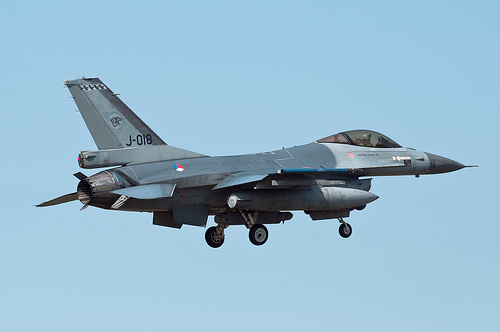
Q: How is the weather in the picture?
A: It is clear.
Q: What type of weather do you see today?
A: It is clear.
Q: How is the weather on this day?
A: It is clear.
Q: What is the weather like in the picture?
A: It is clear.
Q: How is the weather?
A: It is clear.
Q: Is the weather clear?
A: Yes, it is clear.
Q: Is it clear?
A: Yes, it is clear.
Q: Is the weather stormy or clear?
A: It is clear.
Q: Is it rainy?
A: No, it is clear.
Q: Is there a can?
A: No, there are no cans.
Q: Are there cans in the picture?
A: No, there are no cans.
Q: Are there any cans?
A: No, there are no cans.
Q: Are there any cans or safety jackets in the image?
A: No, there are no cans or safety jackets.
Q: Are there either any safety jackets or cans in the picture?
A: No, there are no cans or safety jackets.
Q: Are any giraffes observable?
A: No, there are no giraffes.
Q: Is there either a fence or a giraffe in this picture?
A: No, there are no giraffes or fences.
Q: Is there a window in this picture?
A: Yes, there is a window.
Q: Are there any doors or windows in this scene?
A: Yes, there is a window.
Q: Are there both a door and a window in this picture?
A: No, there is a window but no doors.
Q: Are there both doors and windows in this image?
A: No, there is a window but no doors.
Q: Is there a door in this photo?
A: No, there are no doors.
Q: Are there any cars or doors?
A: No, there are no doors or cars.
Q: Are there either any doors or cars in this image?
A: No, there are no doors or cars.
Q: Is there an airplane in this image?
A: Yes, there is an airplane.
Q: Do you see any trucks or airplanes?
A: Yes, there is an airplane.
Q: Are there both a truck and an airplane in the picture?
A: No, there is an airplane but no trucks.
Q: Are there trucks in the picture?
A: No, there are no trucks.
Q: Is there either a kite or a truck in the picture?
A: No, there are no trucks or kites.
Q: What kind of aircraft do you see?
A: The aircraft is an airplane.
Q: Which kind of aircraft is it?
A: The aircraft is an airplane.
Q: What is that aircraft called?
A: This is an airplane.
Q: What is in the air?
A: The plane is in the air.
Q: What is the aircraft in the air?
A: The aircraft is an airplane.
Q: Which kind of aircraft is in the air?
A: The aircraft is an airplane.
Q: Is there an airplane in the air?
A: Yes, there is an airplane in the air.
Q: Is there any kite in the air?
A: No, there is an airplane in the air.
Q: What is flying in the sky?
A: The airplane is flying in the sky.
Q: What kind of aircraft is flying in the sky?
A: The aircraft is an airplane.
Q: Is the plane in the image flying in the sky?
A: Yes, the plane is flying in the sky.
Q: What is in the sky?
A: The airplane is in the sky.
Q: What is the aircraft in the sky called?
A: The aircraft is an airplane.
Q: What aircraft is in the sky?
A: The aircraft is an airplane.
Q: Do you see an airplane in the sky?
A: Yes, there is an airplane in the sky.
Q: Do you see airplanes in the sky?
A: Yes, there is an airplane in the sky.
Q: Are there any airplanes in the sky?
A: Yes, there is an airplane in the sky.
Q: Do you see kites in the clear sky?
A: No, there is an airplane in the sky.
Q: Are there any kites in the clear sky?
A: No, there is an airplane in the sky.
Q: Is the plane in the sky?
A: Yes, the plane is in the sky.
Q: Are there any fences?
A: No, there are no fences.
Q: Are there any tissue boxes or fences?
A: No, there are no fences or tissue boxes.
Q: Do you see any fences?
A: No, there are no fences.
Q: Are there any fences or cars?
A: No, there are no fences or cars.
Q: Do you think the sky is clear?
A: Yes, the sky is clear.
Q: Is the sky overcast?
A: No, the sky is clear.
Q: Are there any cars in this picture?
A: No, there are no cars.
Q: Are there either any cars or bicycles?
A: No, there are no cars or bicycles.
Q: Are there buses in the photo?
A: No, there are no buses.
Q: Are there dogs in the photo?
A: No, there are no dogs.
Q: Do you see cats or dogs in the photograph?
A: No, there are no dogs or cats.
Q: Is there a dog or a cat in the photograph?
A: No, there are no dogs or cats.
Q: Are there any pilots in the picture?
A: Yes, there is a pilot.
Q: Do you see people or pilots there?
A: Yes, there is a pilot.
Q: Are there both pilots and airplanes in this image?
A: Yes, there are both a pilot and an airplane.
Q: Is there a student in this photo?
A: No, there are no students.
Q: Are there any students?
A: No, there are no students.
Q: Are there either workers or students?
A: No, there are no students or workers.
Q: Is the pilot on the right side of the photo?
A: Yes, the pilot is on the right of the image.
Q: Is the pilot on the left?
A: No, the pilot is on the right of the image.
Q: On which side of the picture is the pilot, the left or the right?
A: The pilot is on the right of the image.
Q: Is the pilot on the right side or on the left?
A: The pilot is on the right of the image.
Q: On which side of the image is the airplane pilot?
A: The pilot is on the right of the image.